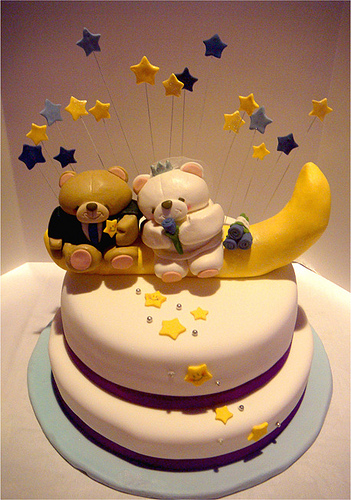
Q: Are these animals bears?
A: Yes, all the animals are bears.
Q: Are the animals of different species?
A: No, all the animals are bears.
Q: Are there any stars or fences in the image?
A: Yes, there is a star.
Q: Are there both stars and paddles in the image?
A: No, there is a star but no paddles.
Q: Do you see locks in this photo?
A: No, there are no locks.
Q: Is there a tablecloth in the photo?
A: Yes, there is a tablecloth.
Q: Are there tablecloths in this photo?
A: Yes, there is a tablecloth.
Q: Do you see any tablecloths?
A: Yes, there is a tablecloth.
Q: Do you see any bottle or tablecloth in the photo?
A: Yes, there is a tablecloth.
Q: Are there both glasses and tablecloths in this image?
A: No, there is a tablecloth but no glasses.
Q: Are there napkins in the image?
A: No, there are no napkins.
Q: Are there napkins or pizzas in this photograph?
A: No, there are no napkins or pizzas.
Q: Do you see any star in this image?
A: Yes, there is a star.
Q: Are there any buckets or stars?
A: Yes, there is a star.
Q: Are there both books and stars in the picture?
A: No, there is a star but no books.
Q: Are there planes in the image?
A: No, there are no planes.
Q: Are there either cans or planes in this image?
A: No, there are no planes or cans.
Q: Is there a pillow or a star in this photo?
A: Yes, there is a star.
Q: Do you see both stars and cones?
A: No, there is a star but no cones.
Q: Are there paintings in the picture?
A: No, there are no paintings.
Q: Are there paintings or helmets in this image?
A: No, there are no paintings or helmets.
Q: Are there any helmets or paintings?
A: No, there are no paintings or helmets.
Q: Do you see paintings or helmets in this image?
A: No, there are no paintings or helmets.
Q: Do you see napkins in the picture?
A: No, there are no napkins.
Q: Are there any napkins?
A: No, there are no napkins.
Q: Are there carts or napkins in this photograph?
A: No, there are no napkins or carts.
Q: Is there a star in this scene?
A: Yes, there is a star.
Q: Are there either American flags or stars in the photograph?
A: Yes, there is a star.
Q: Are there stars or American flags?
A: Yes, there is a star.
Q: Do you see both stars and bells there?
A: No, there is a star but no bells.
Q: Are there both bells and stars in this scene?
A: No, there is a star but no bells.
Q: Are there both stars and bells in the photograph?
A: No, there is a star but no bells.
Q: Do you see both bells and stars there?
A: No, there is a star but no bells.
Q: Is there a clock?
A: No, there are no clocks.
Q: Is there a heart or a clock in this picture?
A: No, there are no clocks or hearts.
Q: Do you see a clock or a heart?
A: No, there are no clocks or hearts.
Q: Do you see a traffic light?
A: No, there are no traffic lights.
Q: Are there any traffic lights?
A: No, there are no traffic lights.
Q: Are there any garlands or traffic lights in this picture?
A: No, there are no traffic lights or garlands.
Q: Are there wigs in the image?
A: No, there are no wigs.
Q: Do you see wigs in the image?
A: No, there are no wigs.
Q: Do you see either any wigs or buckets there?
A: No, there are no wigs or buckets.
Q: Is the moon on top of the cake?
A: Yes, the moon is on top of the cake.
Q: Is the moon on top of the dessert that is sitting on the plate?
A: Yes, the moon is on top of the cake.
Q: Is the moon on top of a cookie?
A: No, the moon is on top of the cake.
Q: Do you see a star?
A: Yes, there is a star.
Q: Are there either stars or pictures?
A: Yes, there is a star.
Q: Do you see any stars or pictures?
A: Yes, there is a star.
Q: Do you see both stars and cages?
A: No, there is a star but no cages.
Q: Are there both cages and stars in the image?
A: No, there is a star but no cages.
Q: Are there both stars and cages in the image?
A: No, there is a star but no cages.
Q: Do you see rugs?
A: No, there are no rugs.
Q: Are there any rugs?
A: No, there are no rugs.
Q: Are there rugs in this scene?
A: No, there are no rugs.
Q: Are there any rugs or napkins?
A: No, there are no rugs or napkins.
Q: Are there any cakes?
A: Yes, there is a cake.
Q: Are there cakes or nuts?
A: Yes, there is a cake.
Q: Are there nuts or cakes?
A: Yes, there is a cake.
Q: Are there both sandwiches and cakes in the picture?
A: No, there is a cake but no sandwiches.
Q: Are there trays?
A: No, there are no trays.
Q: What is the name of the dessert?
A: The dessert is a cake.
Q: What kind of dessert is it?
A: The dessert is a cake.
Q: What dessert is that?
A: This is a cake.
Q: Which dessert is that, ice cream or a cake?
A: This is a cake.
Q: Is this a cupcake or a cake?
A: This is a cake.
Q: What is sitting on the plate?
A: The cake is sitting on the plate.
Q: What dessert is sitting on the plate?
A: The dessert is a cake.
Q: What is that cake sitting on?
A: The cake is sitting on the plate.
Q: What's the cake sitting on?
A: The cake is sitting on the plate.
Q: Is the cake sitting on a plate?
A: Yes, the cake is sitting on a plate.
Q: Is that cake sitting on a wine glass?
A: No, the cake is sitting on a plate.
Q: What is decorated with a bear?
A: The cake is decorated with a bear.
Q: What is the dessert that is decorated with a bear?
A: The dessert is a cake.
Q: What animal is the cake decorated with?
A: The cake is decorated with a bear.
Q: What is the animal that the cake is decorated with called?
A: The animal is a bear.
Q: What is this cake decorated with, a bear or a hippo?
A: The cake is decorated with a bear.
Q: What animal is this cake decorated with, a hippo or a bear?
A: The cake is decorated with a bear.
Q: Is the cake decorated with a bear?
A: Yes, the cake is decorated with a bear.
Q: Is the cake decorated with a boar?
A: No, the cake is decorated with a bear.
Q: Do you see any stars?
A: Yes, there is a star.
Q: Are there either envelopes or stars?
A: Yes, there is a star.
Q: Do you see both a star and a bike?
A: No, there is a star but no bikes.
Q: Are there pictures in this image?
A: No, there are no pictures.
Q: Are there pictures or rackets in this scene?
A: No, there are no pictures or rackets.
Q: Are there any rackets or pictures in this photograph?
A: No, there are no pictures or rackets.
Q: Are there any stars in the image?
A: Yes, there is a star.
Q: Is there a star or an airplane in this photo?
A: Yes, there is a star.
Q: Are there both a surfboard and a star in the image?
A: No, there is a star but no surfboards.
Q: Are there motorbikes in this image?
A: No, there are no motorbikes.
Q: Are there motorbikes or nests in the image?
A: No, there are no motorbikes or nests.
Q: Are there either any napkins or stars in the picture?
A: Yes, there is a star.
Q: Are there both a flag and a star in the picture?
A: No, there is a star but no flags.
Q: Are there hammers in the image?
A: No, there are no hammers.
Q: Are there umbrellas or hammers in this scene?
A: No, there are no hammers or umbrellas.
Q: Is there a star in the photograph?
A: Yes, there is a star.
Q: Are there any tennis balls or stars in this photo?
A: Yes, there is a star.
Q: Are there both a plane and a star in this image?
A: No, there is a star but no airplanes.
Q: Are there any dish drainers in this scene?
A: No, there are no dish drainers.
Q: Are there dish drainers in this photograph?
A: No, there are no dish drainers.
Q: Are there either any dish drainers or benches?
A: No, there are no dish drainers or benches.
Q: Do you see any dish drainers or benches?
A: No, there are no dish drainers or benches.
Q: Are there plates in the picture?
A: Yes, there is a plate.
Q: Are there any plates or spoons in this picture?
A: Yes, there is a plate.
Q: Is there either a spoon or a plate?
A: Yes, there is a plate.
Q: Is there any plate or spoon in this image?
A: Yes, there is a plate.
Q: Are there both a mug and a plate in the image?
A: No, there is a plate but no mugs.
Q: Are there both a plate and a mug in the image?
A: No, there is a plate but no mugs.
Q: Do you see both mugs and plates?
A: No, there is a plate but no mugs.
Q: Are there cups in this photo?
A: No, there are no cups.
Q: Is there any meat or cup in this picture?
A: No, there are no cups or meat.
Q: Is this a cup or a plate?
A: This is a plate.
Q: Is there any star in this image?
A: Yes, there is a star.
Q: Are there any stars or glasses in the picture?
A: Yes, there is a star.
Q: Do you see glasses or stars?
A: Yes, there is a star.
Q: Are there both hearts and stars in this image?
A: No, there is a star but no hearts.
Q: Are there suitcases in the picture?
A: No, there are no suitcases.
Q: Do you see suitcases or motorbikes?
A: No, there are no suitcases or motorbikes.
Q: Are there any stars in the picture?
A: Yes, there is a star.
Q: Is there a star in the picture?
A: Yes, there is a star.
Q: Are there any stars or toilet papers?
A: Yes, there is a star.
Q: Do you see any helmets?
A: No, there are no helmets.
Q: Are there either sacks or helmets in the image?
A: No, there are no helmets or sacks.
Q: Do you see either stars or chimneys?
A: Yes, there is a star.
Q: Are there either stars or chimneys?
A: Yes, there is a star.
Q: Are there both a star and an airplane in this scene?
A: No, there is a star but no airplanes.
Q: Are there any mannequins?
A: No, there are no mannequins.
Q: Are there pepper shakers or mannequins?
A: No, there are no mannequins or pepper shakers.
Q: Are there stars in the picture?
A: Yes, there is a star.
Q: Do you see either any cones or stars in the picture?
A: Yes, there is a star.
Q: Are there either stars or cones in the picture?
A: Yes, there is a star.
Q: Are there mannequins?
A: No, there are no mannequins.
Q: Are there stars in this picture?
A: Yes, there is a star.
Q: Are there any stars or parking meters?
A: Yes, there is a star.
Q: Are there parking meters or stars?
A: Yes, there is a star.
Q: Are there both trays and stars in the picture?
A: No, there is a star but no trays.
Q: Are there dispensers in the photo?
A: No, there are no dispensers.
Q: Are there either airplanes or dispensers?
A: No, there are no dispensers or airplanes.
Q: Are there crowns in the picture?
A: Yes, there is a crown.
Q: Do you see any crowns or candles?
A: Yes, there is a crown.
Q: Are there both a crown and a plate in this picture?
A: Yes, there are both a crown and a plate.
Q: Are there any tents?
A: No, there are no tents.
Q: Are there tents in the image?
A: No, there are no tents.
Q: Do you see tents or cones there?
A: No, there are no tents or cones.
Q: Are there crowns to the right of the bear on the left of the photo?
A: Yes, there is a crown to the right of the bear.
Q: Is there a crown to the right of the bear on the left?
A: Yes, there is a crown to the right of the bear.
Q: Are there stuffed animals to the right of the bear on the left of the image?
A: No, there is a crown to the right of the bear.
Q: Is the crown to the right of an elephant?
A: No, the crown is to the right of a bear.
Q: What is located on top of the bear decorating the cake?
A: The crown is on top of the bear.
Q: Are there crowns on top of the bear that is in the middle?
A: Yes, there is a crown on top of the bear.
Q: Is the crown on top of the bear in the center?
A: Yes, the crown is on top of the bear.